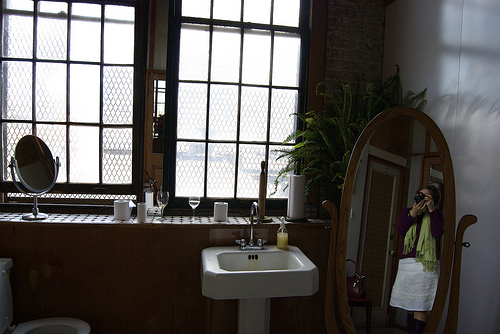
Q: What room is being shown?
A: Bathroom.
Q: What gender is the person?
A: Female.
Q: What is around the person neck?
A: Scarf.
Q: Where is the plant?
A: Corner.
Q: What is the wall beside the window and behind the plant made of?
A: Brick.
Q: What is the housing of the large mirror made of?
A: Wood.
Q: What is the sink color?
A: White.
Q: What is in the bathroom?
A: A mirror.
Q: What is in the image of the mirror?
A: A woman.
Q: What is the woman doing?
A: Taking a picture.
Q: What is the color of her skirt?
A: White skirt.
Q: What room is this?
A: The bathroom.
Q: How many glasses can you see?
A: Two glasses.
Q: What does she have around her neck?
A: She have a scarf.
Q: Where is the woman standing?
A: In front of a big mirror.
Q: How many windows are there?
A: Two windows.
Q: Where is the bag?
A: Bag is on a chair.